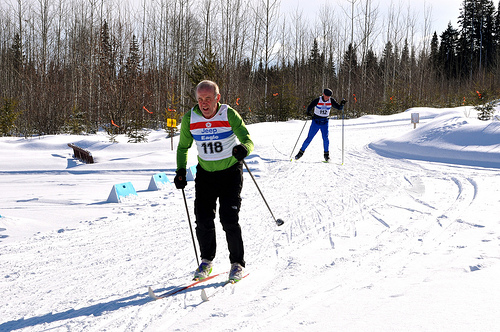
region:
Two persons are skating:
[154, 61, 344, 293]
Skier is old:
[160, 72, 291, 307]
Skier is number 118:
[160, 65, 284, 290]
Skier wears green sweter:
[147, 72, 295, 302]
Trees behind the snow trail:
[4, 4, 492, 116]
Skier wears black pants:
[165, 72, 290, 294]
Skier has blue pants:
[278, 74, 365, 176]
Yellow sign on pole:
[162, 114, 179, 149]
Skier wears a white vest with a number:
[285, 80, 353, 170]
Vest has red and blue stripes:
[178, 108, 242, 165]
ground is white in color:
[342, 206, 436, 291]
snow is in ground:
[325, 215, 418, 285]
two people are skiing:
[186, 73, 346, 188]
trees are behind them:
[23, 24, 427, 79]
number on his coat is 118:
[191, 136, 233, 154]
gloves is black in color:
[171, 166, 195, 197]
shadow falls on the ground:
[20, 274, 139, 320]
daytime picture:
[36, 31, 473, 290]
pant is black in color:
[198, 186, 230, 217]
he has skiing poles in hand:
[161, 161, 305, 256]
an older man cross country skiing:
[161, 78, 290, 304]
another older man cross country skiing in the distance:
[287, 80, 355, 171]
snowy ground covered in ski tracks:
[283, 184, 482, 301]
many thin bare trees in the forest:
[17, 10, 167, 124]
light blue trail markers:
[105, 168, 169, 199]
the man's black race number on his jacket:
[197, 140, 227, 157]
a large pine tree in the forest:
[451, 5, 498, 68]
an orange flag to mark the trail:
[271, 90, 280, 106]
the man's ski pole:
[227, 146, 294, 235]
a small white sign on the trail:
[407, 110, 421, 131]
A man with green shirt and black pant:
[175, 77, 254, 284]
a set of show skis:
[145, 266, 250, 300]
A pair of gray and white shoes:
[189, 260, 250, 282]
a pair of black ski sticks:
[173, 138, 286, 288]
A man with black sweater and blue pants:
[294, 80, 348, 165]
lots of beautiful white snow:
[0, 103, 499, 329]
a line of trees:
[0, 0, 499, 137]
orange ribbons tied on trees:
[97, 88, 498, 130]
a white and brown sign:
[407, 110, 421, 129]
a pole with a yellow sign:
[165, 112, 177, 152]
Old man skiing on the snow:
[162, 61, 282, 293]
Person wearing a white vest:
[290, 80, 360, 175]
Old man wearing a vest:
[157, 65, 292, 306]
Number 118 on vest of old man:
[190, 137, 227, 159]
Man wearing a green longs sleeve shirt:
[161, 60, 284, 290]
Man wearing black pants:
[157, 76, 304, 292]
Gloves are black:
[170, 140, 253, 183]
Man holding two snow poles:
[156, 65, 299, 306]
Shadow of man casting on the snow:
[0, 265, 223, 326]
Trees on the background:
[7, 8, 498, 140]